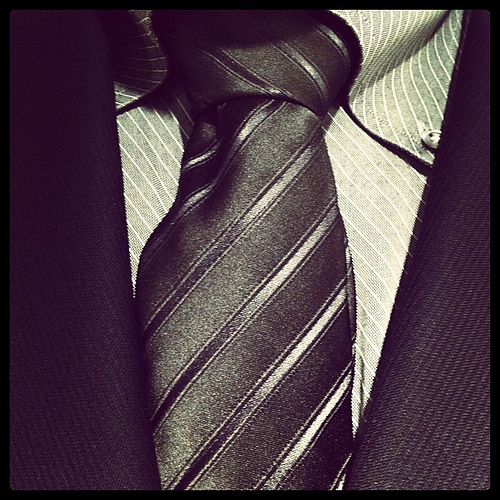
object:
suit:
[0, 0, 500, 500]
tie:
[133, 0, 361, 500]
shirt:
[119, 5, 457, 492]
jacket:
[0, 0, 499, 500]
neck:
[107, 9, 442, 82]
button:
[420, 129, 446, 151]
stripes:
[328, 154, 407, 251]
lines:
[143, 125, 325, 340]